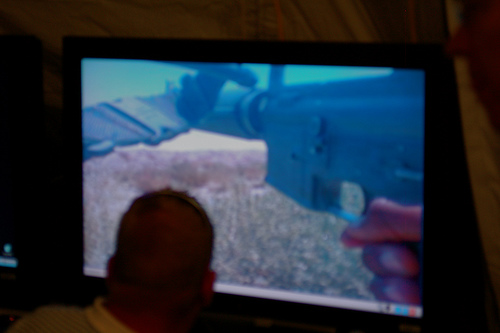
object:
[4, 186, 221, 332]
man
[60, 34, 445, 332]
tv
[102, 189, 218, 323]
hair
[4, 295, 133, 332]
shirt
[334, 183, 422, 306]
person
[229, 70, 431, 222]
gun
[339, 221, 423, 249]
finger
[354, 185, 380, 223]
trigger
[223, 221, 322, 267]
ground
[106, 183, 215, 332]
head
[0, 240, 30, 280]
computer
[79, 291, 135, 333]
collar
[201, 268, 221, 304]
ear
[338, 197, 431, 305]
hand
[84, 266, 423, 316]
bar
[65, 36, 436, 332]
rectangular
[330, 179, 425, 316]
handle